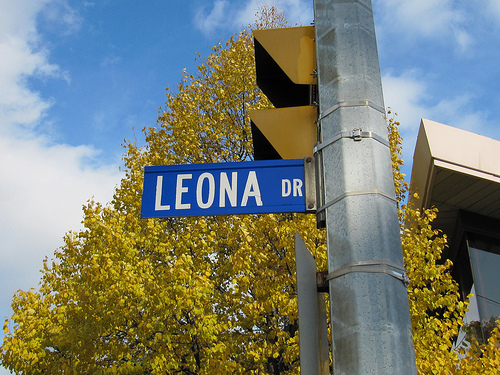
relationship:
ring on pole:
[315, 189, 399, 214] [312, 0, 418, 375]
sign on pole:
[137, 160, 308, 215] [311, 3, 416, 374]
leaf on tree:
[164, 294, 186, 319] [19, 3, 499, 355]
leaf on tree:
[201, 259, 212, 272] [19, 3, 499, 355]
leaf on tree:
[196, 239, 208, 251] [19, 3, 499, 355]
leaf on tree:
[107, 247, 141, 274] [19, 3, 499, 355]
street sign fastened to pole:
[138, 156, 319, 220] [295, 1, 432, 373]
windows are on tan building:
[445, 210, 499, 370] [399, 117, 499, 373]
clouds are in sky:
[3, 45, 62, 196] [98, 20, 195, 118]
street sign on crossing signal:
[155, 128, 341, 220] [249, 18, 318, 158]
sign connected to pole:
[140, 160, 307, 218] [311, 3, 416, 374]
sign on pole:
[140, 160, 307, 218] [303, 4, 418, 318]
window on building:
[455, 236, 495, 334] [390, 97, 496, 326]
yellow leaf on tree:
[452, 315, 467, 328] [19, 3, 499, 355]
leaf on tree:
[1, 315, 13, 332] [125, 45, 359, 355]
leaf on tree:
[411, 189, 422, 201] [401, 188, 481, 368]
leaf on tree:
[429, 205, 439, 215] [19, 3, 499, 355]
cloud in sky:
[4, 11, 124, 197] [39, 20, 252, 162]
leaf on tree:
[162, 122, 167, 127] [19, 3, 499, 355]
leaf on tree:
[393, 110, 399, 115] [19, 3, 499, 355]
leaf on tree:
[272, 350, 279, 357] [19, 3, 499, 355]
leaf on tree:
[468, 293, 475, 298] [19, 3, 499, 355]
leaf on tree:
[413, 192, 418, 199] [19, 3, 499, 355]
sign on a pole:
[140, 160, 307, 218] [289, 44, 434, 369]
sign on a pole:
[137, 160, 308, 215] [311, 3, 416, 374]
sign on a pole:
[140, 160, 307, 218] [262, 5, 445, 332]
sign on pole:
[140, 160, 307, 218] [302, 48, 477, 370]